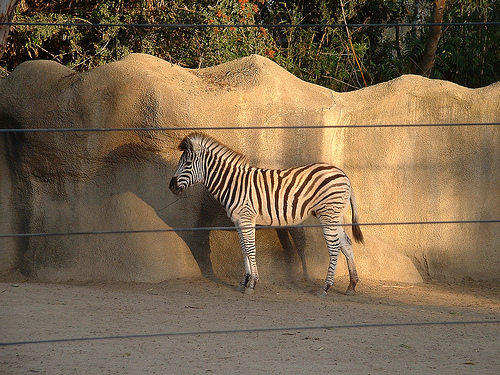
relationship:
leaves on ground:
[293, 324, 449, 373] [1, 274, 495, 372]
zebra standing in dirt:
[169, 129, 367, 298] [4, 284, 498, 373]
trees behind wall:
[4, 7, 498, 88] [8, 51, 498, 298]